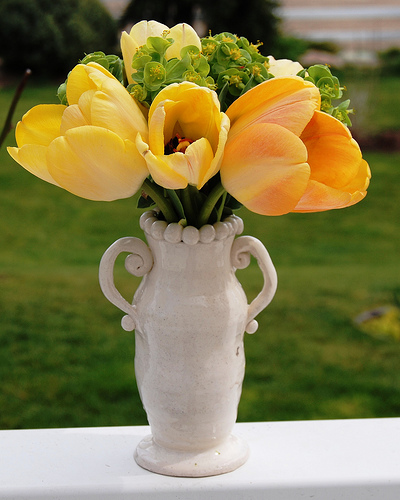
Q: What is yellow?
A: Flowers.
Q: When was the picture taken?
A: Daytime.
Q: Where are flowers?
A: In a vase.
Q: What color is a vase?
A: White.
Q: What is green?
A: Grass.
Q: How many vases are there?
A: One.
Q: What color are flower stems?
A: Green.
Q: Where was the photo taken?
A: On a sundeck.